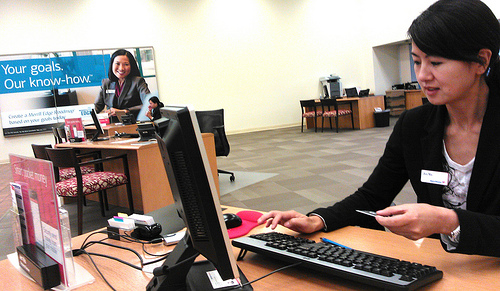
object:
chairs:
[299, 99, 354, 133]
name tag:
[420, 170, 451, 186]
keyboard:
[229, 232, 443, 290]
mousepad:
[226, 210, 267, 240]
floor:
[279, 131, 371, 179]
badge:
[420, 169, 450, 186]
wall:
[3, 0, 372, 134]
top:
[304, 97, 500, 259]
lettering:
[0, 61, 92, 91]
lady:
[256, 0, 500, 258]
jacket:
[306, 104, 499, 256]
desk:
[305, 95, 387, 131]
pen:
[318, 237, 355, 249]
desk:
[0, 205, 499, 290]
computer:
[135, 105, 256, 291]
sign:
[0, 44, 159, 138]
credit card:
[355, 210, 386, 217]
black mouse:
[223, 213, 242, 229]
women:
[92, 0, 499, 258]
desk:
[55, 132, 220, 216]